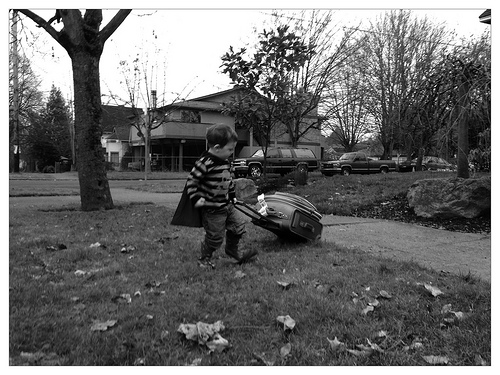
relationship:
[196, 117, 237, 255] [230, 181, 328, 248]
boy drags trolley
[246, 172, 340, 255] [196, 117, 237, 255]
trolley behind boy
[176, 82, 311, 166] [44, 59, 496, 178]
house in background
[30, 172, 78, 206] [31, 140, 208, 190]
sidewalk by street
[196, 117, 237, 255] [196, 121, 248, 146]
boy has hair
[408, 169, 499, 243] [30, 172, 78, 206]
rock by sidewalk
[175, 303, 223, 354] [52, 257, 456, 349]
leaf on ground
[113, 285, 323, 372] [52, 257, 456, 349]
leaves on ground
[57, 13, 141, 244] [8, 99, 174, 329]
tree in yard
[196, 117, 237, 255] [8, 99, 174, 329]
boy in yard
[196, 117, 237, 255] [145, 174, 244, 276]
boy has cape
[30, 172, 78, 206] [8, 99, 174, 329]
sidewalk by yard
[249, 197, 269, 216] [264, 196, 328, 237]
tag on suitcase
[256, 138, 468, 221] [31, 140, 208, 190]
parked along street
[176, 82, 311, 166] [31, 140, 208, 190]
house by street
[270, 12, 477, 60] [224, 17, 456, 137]
wire for telephone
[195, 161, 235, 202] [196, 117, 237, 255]
shirt on boy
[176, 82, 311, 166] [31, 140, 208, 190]
house across street